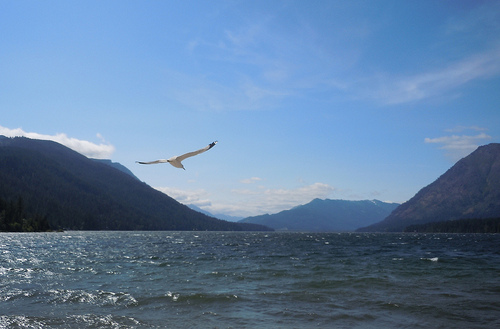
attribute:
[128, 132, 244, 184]
white bird — is flying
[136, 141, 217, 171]
bird — is flying, white, black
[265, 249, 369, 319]
water — calm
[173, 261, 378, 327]
water — calm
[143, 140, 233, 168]
bird — is flying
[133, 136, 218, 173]
bird — is flying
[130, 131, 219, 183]
white bird — is flying